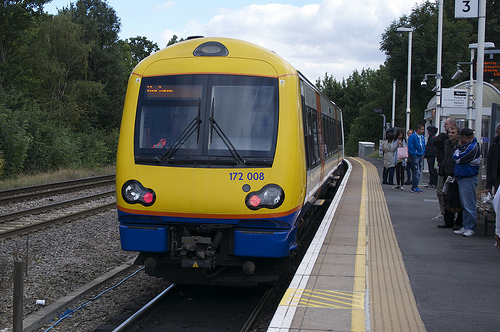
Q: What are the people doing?
A: Waiting for a train.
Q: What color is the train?
A: Blue and yellow.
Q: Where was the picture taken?
A: A train station.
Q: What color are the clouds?
A: White.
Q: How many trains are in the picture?
A: One.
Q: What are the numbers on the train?
A: 172 008.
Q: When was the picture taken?
A: During the day.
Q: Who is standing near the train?
A: People.